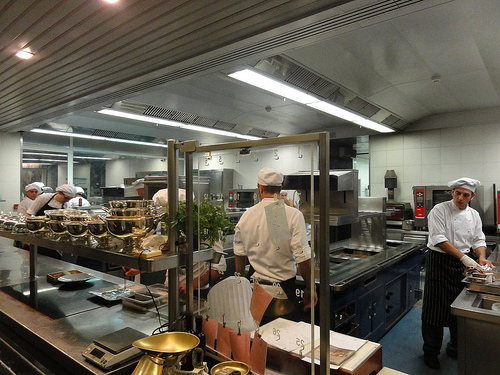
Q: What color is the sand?
A: Tan.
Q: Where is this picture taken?
A: A kitchen.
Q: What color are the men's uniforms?
A: White.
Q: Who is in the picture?
A: Chefs.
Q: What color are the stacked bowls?
A: Silver.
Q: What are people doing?
A: Cooking.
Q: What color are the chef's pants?
A: Black.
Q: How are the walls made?
A: Of tile.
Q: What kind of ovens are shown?
A: Industrial.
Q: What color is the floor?
A: Blue.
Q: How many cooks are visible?
A: 4.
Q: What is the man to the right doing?
A: Cutting.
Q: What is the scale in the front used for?
A: Food.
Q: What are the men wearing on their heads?
A: Hats.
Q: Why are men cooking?
A: For guests.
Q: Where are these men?
A: In the kitchen.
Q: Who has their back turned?
A: A cook.